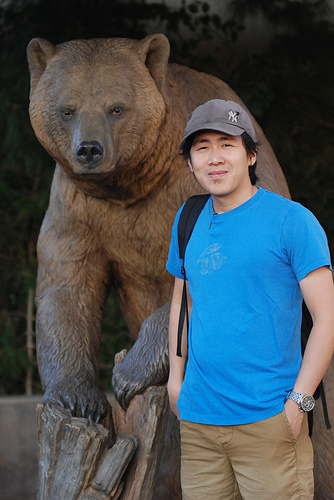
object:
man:
[166, 100, 332, 499]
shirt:
[165, 187, 333, 427]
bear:
[26, 34, 291, 423]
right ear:
[136, 32, 170, 110]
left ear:
[27, 37, 57, 97]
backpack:
[176, 194, 334, 439]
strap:
[174, 193, 210, 359]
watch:
[285, 390, 316, 413]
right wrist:
[287, 389, 307, 413]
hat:
[176, 98, 256, 151]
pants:
[179, 409, 313, 499]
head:
[27, 34, 169, 181]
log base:
[34, 349, 332, 499]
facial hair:
[210, 178, 224, 186]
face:
[189, 133, 247, 195]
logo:
[226, 110, 237, 123]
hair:
[176, 129, 262, 187]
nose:
[74, 138, 104, 169]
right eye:
[108, 106, 126, 119]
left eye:
[60, 105, 73, 119]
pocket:
[275, 411, 296, 448]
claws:
[93, 414, 100, 425]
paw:
[44, 401, 53, 412]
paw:
[123, 390, 132, 408]